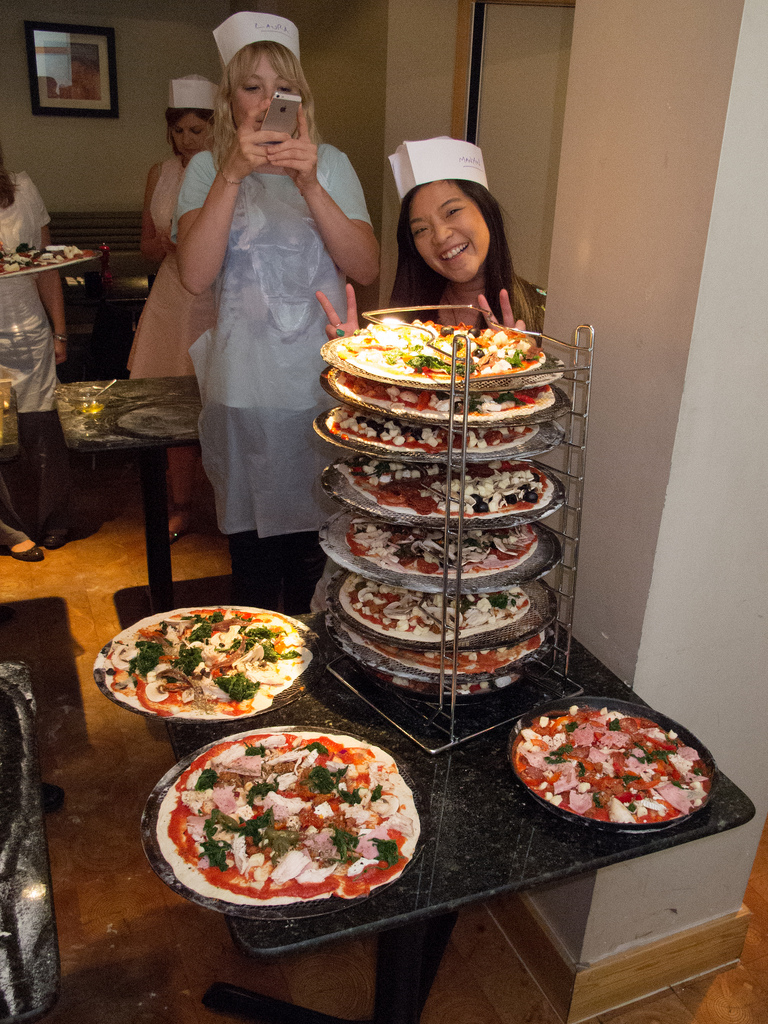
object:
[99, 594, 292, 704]
uncooked pizza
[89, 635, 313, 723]
metal tray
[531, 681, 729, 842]
tray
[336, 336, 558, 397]
pizza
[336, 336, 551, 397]
tray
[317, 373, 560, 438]
pizza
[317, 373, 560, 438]
tray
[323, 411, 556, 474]
pizza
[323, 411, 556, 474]
tray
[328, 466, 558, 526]
pizza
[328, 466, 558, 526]
tray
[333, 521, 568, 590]
pizza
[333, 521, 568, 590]
tray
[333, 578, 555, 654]
tray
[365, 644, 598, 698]
pizza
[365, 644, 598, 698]
tray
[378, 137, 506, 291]
head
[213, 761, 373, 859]
toppings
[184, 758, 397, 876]
pizza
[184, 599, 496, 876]
surface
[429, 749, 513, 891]
table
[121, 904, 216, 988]
ground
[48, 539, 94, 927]
light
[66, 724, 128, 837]
ground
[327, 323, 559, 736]
pizzas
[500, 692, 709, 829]
pizza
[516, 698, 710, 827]
pan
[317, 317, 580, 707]
pans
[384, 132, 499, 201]
chef hat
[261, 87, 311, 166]
phone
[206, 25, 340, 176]
girl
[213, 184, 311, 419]
apron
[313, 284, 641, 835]
pizzas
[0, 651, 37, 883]
bowl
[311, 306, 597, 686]
pizza rack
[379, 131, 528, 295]
girl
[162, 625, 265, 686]
toppings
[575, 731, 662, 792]
toppings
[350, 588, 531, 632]
pizza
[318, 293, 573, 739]
stack